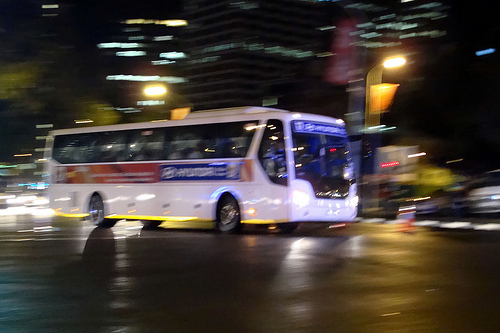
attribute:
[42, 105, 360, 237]
bus — white, moving, public, speeding, going quickly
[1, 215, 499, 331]
street — black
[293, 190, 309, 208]
front light — lit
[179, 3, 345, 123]
building — tall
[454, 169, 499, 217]
car — white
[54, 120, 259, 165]
windows — glass, tinted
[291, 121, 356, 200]
windshield — large